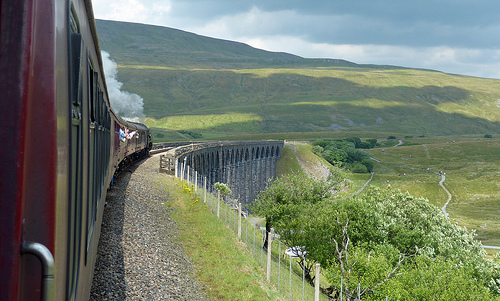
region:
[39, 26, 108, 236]
this is a train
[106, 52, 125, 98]
these are the fumes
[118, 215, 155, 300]
these are the small rocks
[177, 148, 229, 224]
this is a fence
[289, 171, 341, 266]
this is a tree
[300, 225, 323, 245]
the tree has green leaves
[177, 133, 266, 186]
this is a bridge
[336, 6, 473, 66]
this is the sky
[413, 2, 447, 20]
the sky is blue in color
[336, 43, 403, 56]
these are the clouds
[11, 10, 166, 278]
Red and green train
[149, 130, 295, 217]
Long, tall grey bridge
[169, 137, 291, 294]
Grey fence with brown posts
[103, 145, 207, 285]
Gravel next to the track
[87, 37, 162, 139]
Plume of grey smoke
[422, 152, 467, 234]
Grey road over the hillside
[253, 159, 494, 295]
Trees behind the fence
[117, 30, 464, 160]
Clouds drop shadows on the hills below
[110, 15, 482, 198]
A green, grassy hillside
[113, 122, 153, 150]
A person sticks their head and arm out of the train window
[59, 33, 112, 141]
windows on passenger train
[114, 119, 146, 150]
people hanging out of windows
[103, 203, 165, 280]
gravel with shadow on ground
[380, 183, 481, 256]
tree tops overlooking valley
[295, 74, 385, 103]
cloud shadow on land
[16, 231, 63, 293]
metal pole on train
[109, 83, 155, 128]
white smoke above train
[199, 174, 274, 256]
fence on grassy hill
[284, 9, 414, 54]
dark clouds on sky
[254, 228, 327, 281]
trees on grassy hill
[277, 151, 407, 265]
The trees are green.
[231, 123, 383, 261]
The trees are green.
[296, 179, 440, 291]
The trees are green.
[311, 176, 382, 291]
The trees are green.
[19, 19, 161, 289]
a train on rails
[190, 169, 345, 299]
a wooden fence in background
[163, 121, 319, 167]
train tracks in background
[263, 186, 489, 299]
trees growing in background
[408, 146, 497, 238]
a small stream of water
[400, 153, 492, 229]
grass growing in background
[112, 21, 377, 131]
a big hill in background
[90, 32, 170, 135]
white smoking coming from train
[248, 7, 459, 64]
dark clouds in the sky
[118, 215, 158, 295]
grey pebbles on the ground